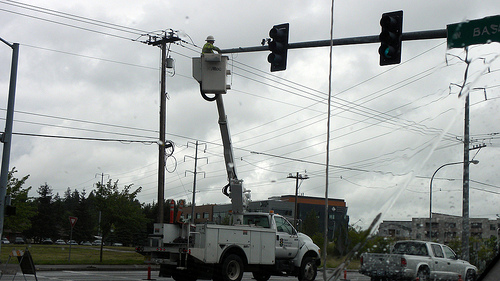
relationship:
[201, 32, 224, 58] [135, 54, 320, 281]
man in truck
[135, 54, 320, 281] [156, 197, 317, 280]
truck in truck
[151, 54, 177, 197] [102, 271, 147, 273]
street pole by street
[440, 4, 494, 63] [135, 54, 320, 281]
street sign behind truck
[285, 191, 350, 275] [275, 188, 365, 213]
buildings with orange roof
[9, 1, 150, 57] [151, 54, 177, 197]
wires on street pole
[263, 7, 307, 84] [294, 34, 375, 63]
traffic light on pole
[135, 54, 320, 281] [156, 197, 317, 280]
truck over truck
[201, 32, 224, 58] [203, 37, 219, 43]
man in hat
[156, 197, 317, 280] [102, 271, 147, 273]
truck in street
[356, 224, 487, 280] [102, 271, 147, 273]
pickup in street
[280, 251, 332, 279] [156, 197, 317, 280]
tires on truck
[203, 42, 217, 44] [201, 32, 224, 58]
head of man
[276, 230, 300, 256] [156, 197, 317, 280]
door on truck